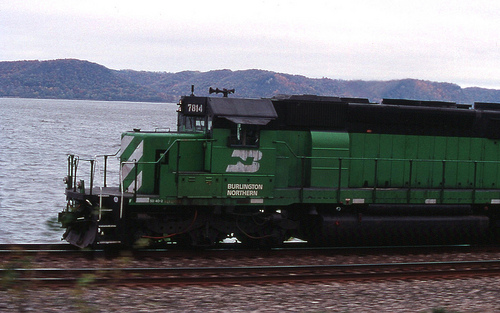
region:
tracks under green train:
[157, 254, 297, 300]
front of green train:
[38, 125, 158, 265]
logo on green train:
[202, 123, 309, 209]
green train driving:
[217, 100, 495, 226]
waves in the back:
[3, 73, 135, 154]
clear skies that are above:
[87, 0, 417, 72]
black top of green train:
[175, 85, 488, 152]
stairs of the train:
[75, 175, 144, 255]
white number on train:
[182, 90, 226, 118]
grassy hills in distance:
[4, 38, 287, 95]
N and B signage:
[226, 148, 262, 171]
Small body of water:
[0, 98, 181, 242]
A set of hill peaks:
[0, 55, 498, 110]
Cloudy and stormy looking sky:
[1, 0, 498, 90]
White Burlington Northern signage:
[225, 183, 262, 196]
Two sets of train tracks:
[1, 241, 498, 292]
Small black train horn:
[208, 85, 237, 97]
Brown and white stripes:
[118, 133, 143, 192]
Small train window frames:
[176, 115, 213, 135]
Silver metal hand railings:
[63, 136, 217, 251]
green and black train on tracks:
[183, 86, 478, 252]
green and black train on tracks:
[73, 128, 176, 263]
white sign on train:
[228, 145, 266, 175]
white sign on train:
[223, 180, 273, 202]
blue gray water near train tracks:
[13, 98, 115, 152]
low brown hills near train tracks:
[8, 61, 189, 99]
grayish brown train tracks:
[20, 265, 492, 277]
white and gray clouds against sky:
[6, 4, 197, 51]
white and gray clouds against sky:
[171, 12, 343, 60]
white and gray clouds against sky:
[295, 14, 475, 71]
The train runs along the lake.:
[0, 81, 498, 249]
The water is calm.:
[3, 96, 58, 238]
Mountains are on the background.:
[0, 56, 495, 96]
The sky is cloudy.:
[5, 0, 490, 60]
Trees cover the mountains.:
[1, 55, 496, 90]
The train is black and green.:
[115, 90, 495, 200]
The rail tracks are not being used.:
[16, 255, 491, 280]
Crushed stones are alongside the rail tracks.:
[2, 285, 492, 305]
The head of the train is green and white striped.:
[117, 130, 145, 191]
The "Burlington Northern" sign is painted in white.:
[225, 180, 265, 195]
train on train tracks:
[57, 87, 354, 280]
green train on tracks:
[52, 76, 341, 251]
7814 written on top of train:
[51, 55, 306, 256]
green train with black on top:
[56, 75, 463, 276]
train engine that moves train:
[56, 85, 343, 262]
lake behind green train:
[12, 43, 368, 285]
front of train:
[90, 66, 291, 298]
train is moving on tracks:
[60, 2, 455, 282]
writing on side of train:
[128, 56, 439, 254]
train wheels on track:
[54, 76, 439, 292]